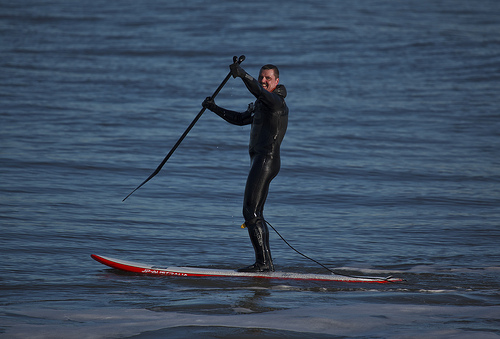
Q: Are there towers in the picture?
A: No, there are no towers.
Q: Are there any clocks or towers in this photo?
A: No, there are no towers or clocks.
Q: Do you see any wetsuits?
A: Yes, there is a wetsuit.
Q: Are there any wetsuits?
A: Yes, there is a wetsuit.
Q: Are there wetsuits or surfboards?
A: Yes, there is a wetsuit.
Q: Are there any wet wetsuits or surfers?
A: Yes, there is a wet wetsuit.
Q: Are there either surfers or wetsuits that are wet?
A: Yes, the wetsuit is wet.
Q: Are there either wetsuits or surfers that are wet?
A: Yes, the wetsuit is wet.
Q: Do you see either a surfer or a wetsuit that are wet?
A: Yes, the wetsuit is wet.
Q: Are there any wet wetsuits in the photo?
A: Yes, there is a wet wetsuit.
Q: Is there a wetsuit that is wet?
A: Yes, there is a wetsuit that is wet.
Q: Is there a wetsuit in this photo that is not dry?
A: Yes, there is a wet wetsuit.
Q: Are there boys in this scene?
A: No, there are no boys.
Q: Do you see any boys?
A: No, there are no boys.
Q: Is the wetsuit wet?
A: Yes, the wetsuit is wet.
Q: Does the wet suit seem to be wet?
A: Yes, the wet suit is wet.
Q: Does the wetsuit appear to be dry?
A: No, the wetsuit is wet.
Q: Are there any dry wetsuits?
A: No, there is a wetsuit but it is wet.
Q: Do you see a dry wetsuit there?
A: No, there is a wetsuit but it is wet.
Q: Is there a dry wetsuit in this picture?
A: No, there is a wetsuit but it is wet.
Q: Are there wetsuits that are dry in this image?
A: No, there is a wetsuit but it is wet.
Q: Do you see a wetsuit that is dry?
A: No, there is a wetsuit but it is wet.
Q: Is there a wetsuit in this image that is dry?
A: No, there is a wetsuit but it is wet.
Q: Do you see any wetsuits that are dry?
A: No, there is a wetsuit but it is wet.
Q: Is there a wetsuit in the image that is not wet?
A: No, there is a wetsuit but it is wet.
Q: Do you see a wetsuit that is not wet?
A: No, there is a wetsuit but it is wet.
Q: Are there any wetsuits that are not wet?
A: No, there is a wetsuit but it is wet.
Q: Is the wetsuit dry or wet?
A: The wetsuit is wet.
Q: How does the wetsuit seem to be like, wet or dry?
A: The wetsuit is wet.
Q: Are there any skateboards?
A: No, there are no skateboards.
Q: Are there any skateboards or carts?
A: No, there are no skateboards or carts.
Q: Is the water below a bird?
A: No, the water is below the paddle.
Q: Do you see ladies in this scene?
A: No, there are no ladies.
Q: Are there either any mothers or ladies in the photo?
A: No, there are no ladies or mothers.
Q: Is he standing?
A: Yes, the man is standing.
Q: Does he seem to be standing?
A: Yes, the man is standing.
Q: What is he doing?
A: The man is standing.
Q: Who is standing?
A: The man is standing.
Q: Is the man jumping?
A: No, the man is standing.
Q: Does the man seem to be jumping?
A: No, the man is standing.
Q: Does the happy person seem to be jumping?
A: No, the man is standing.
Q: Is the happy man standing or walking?
A: The man is standing.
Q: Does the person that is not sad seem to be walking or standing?
A: The man is standing.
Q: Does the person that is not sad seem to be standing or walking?
A: The man is standing.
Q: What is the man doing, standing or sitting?
A: The man is standing.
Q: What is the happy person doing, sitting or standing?
A: The man is standing.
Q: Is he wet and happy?
A: Yes, the man is wet and happy.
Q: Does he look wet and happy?
A: Yes, the man is wet and happy.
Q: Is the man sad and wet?
A: No, the man is wet but happy.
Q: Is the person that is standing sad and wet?
A: No, the man is wet but happy.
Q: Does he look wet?
A: Yes, the man is wet.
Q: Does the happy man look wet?
A: Yes, the man is wet.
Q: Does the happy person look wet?
A: Yes, the man is wet.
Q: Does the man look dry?
A: No, the man is wet.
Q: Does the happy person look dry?
A: No, the man is wet.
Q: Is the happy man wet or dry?
A: The man is wet.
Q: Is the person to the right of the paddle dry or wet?
A: The man is wet.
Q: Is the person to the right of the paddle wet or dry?
A: The man is wet.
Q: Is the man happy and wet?
A: Yes, the man is happy and wet.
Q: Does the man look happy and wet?
A: Yes, the man is happy and wet.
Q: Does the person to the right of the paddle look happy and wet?
A: Yes, the man is happy and wet.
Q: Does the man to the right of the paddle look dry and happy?
A: No, the man is happy but wet.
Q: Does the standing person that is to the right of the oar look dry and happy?
A: No, the man is happy but wet.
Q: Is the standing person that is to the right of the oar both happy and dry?
A: No, the man is happy but wet.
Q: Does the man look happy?
A: Yes, the man is happy.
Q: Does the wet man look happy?
A: Yes, the man is happy.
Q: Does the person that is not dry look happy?
A: Yes, the man is happy.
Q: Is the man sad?
A: No, the man is happy.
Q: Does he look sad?
A: No, the man is happy.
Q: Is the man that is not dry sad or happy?
A: The man is happy.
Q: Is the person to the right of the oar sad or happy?
A: The man is happy.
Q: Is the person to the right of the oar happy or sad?
A: The man is happy.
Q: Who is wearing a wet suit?
A: The man is wearing a wet suit.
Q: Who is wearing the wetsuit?
A: The man is wearing a wet suit.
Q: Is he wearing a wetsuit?
A: Yes, the man is wearing a wetsuit.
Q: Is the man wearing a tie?
A: No, the man is wearing a wetsuit.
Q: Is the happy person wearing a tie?
A: No, the man is wearing a wetsuit.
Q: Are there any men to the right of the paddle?
A: Yes, there is a man to the right of the paddle.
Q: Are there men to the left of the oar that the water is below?
A: No, the man is to the right of the paddle.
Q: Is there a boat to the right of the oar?
A: No, there is a man to the right of the oar.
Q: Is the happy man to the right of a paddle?
A: Yes, the man is to the right of a paddle.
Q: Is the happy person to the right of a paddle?
A: Yes, the man is to the right of a paddle.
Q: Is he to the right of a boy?
A: No, the man is to the right of a paddle.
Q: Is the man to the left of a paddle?
A: No, the man is to the right of a paddle.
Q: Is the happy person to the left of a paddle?
A: No, the man is to the right of a paddle.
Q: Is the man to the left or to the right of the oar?
A: The man is to the right of the oar.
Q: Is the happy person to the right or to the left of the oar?
A: The man is to the right of the oar.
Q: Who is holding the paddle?
A: The man is holding the paddle.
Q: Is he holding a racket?
A: No, the man is holding the oar.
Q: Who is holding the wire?
A: The man is holding the wire.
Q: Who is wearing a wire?
A: The man is wearing a wire.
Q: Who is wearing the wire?
A: The man is wearing a wire.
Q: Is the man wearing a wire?
A: Yes, the man is wearing a wire.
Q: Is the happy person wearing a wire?
A: Yes, the man is wearing a wire.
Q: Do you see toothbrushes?
A: No, there are no toothbrushes.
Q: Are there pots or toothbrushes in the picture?
A: No, there are no toothbrushes or pots.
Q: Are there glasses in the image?
A: No, there are no glasses.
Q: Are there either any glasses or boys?
A: No, there are no glasses or boys.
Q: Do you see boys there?
A: No, there are no boys.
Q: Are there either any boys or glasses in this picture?
A: No, there are no boys or glasses.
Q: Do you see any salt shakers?
A: No, there are no salt shakers.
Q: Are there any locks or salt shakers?
A: No, there are no salt shakers or locks.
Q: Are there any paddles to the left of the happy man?
A: Yes, there is a paddle to the left of the man.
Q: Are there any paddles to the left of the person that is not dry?
A: Yes, there is a paddle to the left of the man.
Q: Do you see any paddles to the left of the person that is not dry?
A: Yes, there is a paddle to the left of the man.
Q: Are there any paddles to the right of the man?
A: No, the paddle is to the left of the man.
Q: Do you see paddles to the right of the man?
A: No, the paddle is to the left of the man.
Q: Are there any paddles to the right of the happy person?
A: No, the paddle is to the left of the man.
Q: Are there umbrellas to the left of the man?
A: No, there is a paddle to the left of the man.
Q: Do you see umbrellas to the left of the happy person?
A: No, there is a paddle to the left of the man.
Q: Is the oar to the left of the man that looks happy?
A: Yes, the oar is to the left of the man.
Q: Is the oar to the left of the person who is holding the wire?
A: Yes, the oar is to the left of the man.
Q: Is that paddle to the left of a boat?
A: No, the paddle is to the left of the man.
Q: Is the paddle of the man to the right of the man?
A: No, the oar is to the left of the man.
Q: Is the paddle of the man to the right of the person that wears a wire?
A: No, the oar is to the left of the man.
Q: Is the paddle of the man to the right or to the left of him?
A: The oar is to the left of the man.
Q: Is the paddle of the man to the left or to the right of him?
A: The oar is to the left of the man.